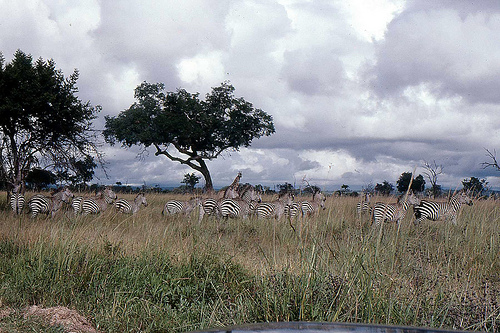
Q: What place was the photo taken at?
A: It was taken at the field.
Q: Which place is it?
A: It is a field.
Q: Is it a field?
A: Yes, it is a field.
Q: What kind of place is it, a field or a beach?
A: It is a field.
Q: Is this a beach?
A: No, it is a field.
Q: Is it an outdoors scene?
A: Yes, it is outdoors.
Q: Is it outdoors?
A: Yes, it is outdoors.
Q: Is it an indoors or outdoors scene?
A: It is outdoors.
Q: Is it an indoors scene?
A: No, it is outdoors.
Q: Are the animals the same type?
A: Yes, all the animals are zebras.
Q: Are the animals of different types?
A: No, all the animals are zebras.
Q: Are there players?
A: No, there are no players.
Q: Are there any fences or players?
A: No, there are no players or fences.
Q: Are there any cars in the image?
A: No, there are no cars.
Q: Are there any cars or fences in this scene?
A: No, there are no cars or fences.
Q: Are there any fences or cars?
A: No, there are no cars or fences.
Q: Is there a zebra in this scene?
A: Yes, there is a zebra.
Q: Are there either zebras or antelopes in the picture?
A: Yes, there is a zebra.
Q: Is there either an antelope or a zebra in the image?
A: Yes, there is a zebra.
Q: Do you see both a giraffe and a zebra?
A: No, there is a zebra but no giraffes.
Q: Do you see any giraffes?
A: No, there are no giraffes.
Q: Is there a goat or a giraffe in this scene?
A: No, there are no giraffes or goats.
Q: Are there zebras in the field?
A: Yes, there is a zebra in the field.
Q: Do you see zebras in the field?
A: Yes, there is a zebra in the field.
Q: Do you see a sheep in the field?
A: No, there is a zebra in the field.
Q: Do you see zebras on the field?
A: Yes, there is a zebra on the field.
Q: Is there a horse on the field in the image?
A: No, there is a zebra on the field.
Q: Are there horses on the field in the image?
A: No, there is a zebra on the field.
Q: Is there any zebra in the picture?
A: Yes, there is a zebra.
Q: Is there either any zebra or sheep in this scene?
A: Yes, there is a zebra.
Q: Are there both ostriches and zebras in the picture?
A: No, there is a zebra but no ostriches.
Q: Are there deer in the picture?
A: No, there are no deer.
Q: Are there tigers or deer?
A: No, there are no deer or tigers.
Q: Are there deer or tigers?
A: No, there are no deer or tigers.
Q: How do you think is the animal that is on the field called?
A: The animal is a zebra.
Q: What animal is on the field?
A: The animal is a zebra.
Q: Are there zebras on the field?
A: Yes, there is a zebra on the field.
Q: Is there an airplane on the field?
A: No, there is a zebra on the field.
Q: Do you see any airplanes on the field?
A: No, there is a zebra on the field.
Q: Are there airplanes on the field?
A: No, there is a zebra on the field.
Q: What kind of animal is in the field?
A: The animal is a zebra.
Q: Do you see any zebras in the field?
A: Yes, there is a zebra in the field.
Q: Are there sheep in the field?
A: No, there is a zebra in the field.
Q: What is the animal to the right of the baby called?
A: The animal is a zebra.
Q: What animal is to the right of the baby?
A: The animal is a zebra.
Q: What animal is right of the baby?
A: The animal is a zebra.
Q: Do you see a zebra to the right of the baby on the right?
A: Yes, there is a zebra to the right of the baby.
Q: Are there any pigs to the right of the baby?
A: No, there is a zebra to the right of the baby.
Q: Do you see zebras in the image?
A: Yes, there is a zebra.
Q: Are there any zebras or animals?
A: Yes, there is a zebra.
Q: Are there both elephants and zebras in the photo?
A: No, there is a zebra but no elephants.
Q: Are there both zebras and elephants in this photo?
A: No, there is a zebra but no elephants.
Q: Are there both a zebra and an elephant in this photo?
A: No, there is a zebra but no elephants.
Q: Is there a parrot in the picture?
A: No, there are no parrots.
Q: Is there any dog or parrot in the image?
A: No, there are no parrots or dogs.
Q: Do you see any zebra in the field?
A: Yes, there is a zebra in the field.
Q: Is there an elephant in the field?
A: No, there is a zebra in the field.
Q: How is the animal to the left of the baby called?
A: The animal is a zebra.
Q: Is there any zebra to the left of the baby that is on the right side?
A: Yes, there is a zebra to the left of the baby.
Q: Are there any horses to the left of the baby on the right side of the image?
A: No, there is a zebra to the left of the baby.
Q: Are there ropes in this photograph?
A: No, there are no ropes.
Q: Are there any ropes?
A: No, there are no ropes.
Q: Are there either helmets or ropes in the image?
A: No, there are no ropes or helmets.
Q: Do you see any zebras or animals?
A: Yes, there is a zebra.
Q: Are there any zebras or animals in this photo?
A: Yes, there is a zebra.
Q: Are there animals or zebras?
A: Yes, there is a zebra.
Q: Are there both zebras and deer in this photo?
A: No, there is a zebra but no deer.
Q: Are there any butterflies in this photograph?
A: No, there are no butterflies.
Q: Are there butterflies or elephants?
A: No, there are no butterflies or elephants.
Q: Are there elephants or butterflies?
A: No, there are no butterflies or elephants.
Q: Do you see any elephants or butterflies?
A: No, there are no butterflies or elephants.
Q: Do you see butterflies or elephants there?
A: No, there are no butterflies or elephants.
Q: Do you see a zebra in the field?
A: Yes, there is a zebra in the field.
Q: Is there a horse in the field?
A: No, there is a zebra in the field.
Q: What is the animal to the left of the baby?
A: The animal is a zebra.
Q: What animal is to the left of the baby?
A: The animal is a zebra.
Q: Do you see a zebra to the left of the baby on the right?
A: Yes, there is a zebra to the left of the baby.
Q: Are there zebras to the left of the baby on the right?
A: Yes, there is a zebra to the left of the baby.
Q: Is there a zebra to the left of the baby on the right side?
A: Yes, there is a zebra to the left of the baby.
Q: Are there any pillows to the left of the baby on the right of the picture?
A: No, there is a zebra to the left of the baby.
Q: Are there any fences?
A: No, there are no fences.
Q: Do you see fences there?
A: No, there are no fences.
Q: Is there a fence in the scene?
A: No, there are no fences.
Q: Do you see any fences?
A: No, there are no fences.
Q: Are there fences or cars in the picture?
A: No, there are no fences or cars.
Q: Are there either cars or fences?
A: No, there are no fences or cars.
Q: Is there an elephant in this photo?
A: No, there are no elephants.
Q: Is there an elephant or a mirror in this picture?
A: No, there are no elephants or mirrors.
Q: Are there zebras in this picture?
A: Yes, there is a zebra.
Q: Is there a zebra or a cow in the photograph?
A: Yes, there is a zebra.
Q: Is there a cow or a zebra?
A: Yes, there is a zebra.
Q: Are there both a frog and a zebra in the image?
A: No, there is a zebra but no frogs.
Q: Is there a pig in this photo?
A: No, there are no pigs.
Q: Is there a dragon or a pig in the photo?
A: No, there are no pigs or dragons.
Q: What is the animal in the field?
A: The animal is a zebra.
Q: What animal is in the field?
A: The animal is a zebra.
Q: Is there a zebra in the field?
A: Yes, there is a zebra in the field.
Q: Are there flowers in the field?
A: No, there is a zebra in the field.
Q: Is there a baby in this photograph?
A: Yes, there is a baby.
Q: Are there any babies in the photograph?
A: Yes, there is a baby.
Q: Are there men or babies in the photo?
A: Yes, there is a baby.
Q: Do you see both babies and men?
A: No, there is a baby but no men.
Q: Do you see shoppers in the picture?
A: No, there are no shoppers.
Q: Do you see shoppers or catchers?
A: No, there are no shoppers or catchers.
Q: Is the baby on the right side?
A: Yes, the baby is on the right of the image.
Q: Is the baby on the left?
A: No, the baby is on the right of the image.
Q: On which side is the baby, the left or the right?
A: The baby is on the right of the image.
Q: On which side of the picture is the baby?
A: The baby is on the right of the image.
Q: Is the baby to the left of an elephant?
A: No, the baby is to the left of the zebra.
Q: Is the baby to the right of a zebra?
A: Yes, the baby is to the right of a zebra.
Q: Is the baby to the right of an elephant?
A: No, the baby is to the right of a zebra.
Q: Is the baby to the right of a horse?
A: No, the baby is to the right of the zebra.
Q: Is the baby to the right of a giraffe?
A: No, the baby is to the right of the zebra.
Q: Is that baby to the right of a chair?
A: No, the baby is to the right of the zebra.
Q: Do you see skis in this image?
A: No, there are no skis.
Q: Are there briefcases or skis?
A: No, there are no skis or briefcases.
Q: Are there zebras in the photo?
A: Yes, there is a zebra.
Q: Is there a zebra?
A: Yes, there is a zebra.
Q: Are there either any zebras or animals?
A: Yes, there is a zebra.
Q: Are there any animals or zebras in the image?
A: Yes, there is a zebra.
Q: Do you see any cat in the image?
A: No, there are no cats.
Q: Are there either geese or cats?
A: No, there are no cats or geese.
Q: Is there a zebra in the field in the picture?
A: Yes, there is a zebra in the field.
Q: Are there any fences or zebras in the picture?
A: Yes, there is a zebra.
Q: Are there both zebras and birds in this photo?
A: No, there is a zebra but no birds.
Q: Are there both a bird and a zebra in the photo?
A: No, there is a zebra but no birds.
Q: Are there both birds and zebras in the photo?
A: No, there is a zebra but no birds.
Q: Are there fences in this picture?
A: No, there are no fences.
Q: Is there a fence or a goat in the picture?
A: No, there are no fences or goats.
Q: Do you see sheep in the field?
A: No, there is a zebra in the field.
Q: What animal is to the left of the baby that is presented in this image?
A: The animal is a zebra.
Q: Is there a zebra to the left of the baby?
A: Yes, there is a zebra to the left of the baby.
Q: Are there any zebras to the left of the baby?
A: Yes, there is a zebra to the left of the baby.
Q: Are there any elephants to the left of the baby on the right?
A: No, there is a zebra to the left of the baby.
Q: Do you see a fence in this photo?
A: No, there are no fences.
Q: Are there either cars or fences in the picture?
A: No, there are no fences or cars.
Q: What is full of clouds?
A: The sky is full of clouds.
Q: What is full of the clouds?
A: The sky is full of clouds.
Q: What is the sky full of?
A: The sky is full of clouds.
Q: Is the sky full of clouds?
A: Yes, the sky is full of clouds.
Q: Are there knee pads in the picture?
A: No, there are no knee pads.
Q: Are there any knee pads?
A: No, there are no knee pads.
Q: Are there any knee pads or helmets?
A: No, there are no knee pads or helmets.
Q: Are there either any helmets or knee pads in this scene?
A: No, there are no knee pads or helmets.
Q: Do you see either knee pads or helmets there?
A: No, there are no knee pads or helmets.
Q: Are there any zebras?
A: Yes, there is a zebra.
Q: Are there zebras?
A: Yes, there is a zebra.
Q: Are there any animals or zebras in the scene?
A: Yes, there is a zebra.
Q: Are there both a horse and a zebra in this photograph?
A: No, there is a zebra but no horses.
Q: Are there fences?
A: No, there are no fences.